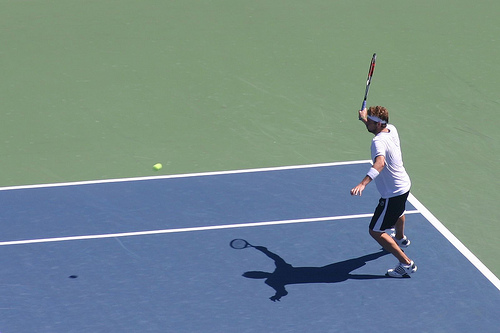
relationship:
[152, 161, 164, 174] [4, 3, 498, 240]
ball in air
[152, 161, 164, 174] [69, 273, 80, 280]
ball left a shadow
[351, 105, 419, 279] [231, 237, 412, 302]
man has a shadow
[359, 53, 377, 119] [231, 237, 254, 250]
racket has a shadow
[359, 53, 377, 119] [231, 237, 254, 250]
racket left a shadow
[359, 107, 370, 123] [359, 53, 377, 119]
man's hand holding racket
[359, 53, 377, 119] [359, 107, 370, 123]
racket held by man's hand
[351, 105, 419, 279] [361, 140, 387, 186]
man has a left arm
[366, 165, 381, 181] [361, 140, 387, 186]
wristband on left arm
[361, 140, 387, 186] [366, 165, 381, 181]
left arm has a wristband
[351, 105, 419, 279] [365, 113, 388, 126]
man wearing headband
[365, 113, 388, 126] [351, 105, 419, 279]
headband being worn by man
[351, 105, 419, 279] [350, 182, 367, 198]
man has a left hand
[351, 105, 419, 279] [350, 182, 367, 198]
man has left hand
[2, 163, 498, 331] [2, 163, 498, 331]
blue on tennis court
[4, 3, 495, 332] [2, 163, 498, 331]
court partially blue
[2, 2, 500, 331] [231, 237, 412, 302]
ground has shadow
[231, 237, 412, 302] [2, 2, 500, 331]
shadow casted on ground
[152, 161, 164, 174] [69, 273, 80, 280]
ball has shadow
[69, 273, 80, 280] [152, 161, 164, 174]
shadow of ball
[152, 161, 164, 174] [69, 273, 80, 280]
ball has a visible shadow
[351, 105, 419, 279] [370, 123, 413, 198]
man wearing shirt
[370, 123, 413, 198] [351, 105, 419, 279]
white shirt worn by a man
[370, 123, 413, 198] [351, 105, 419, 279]
shirt worn by man